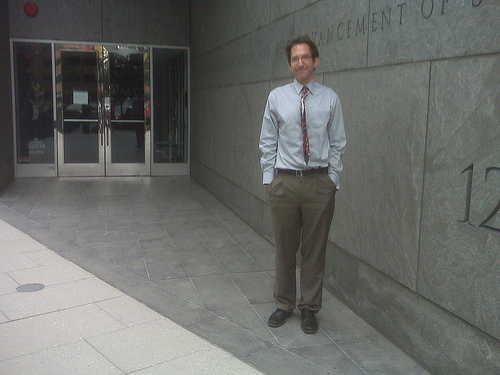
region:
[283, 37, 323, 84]
Man wearing eye glasses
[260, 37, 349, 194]
Man wearing glasses and tie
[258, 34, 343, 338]
Man wearing slacks, shirt, tie, and glasses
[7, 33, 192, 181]
Front door to a building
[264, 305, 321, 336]
Black shoes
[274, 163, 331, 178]
Black belt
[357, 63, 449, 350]
Granite side of a building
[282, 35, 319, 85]
Man with short hair smiling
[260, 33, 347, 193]
Man waring red tie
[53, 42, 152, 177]
Front glass door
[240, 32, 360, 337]
a man standing by the building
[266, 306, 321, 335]
the black dress shoes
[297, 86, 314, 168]
a red tie on the man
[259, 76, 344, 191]
a blue long sleeve shirt tucked in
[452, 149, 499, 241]
the number carved in the wall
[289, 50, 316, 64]
the eye glasses on the mans face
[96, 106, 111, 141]
the rails on the door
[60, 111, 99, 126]
the rail of the door behind the glass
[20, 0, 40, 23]
a red alarm above the door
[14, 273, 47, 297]
a round grate on the ground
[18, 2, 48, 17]
Alarm on the side of the building.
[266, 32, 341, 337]
Man standing outside the building.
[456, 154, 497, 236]
The number 12 on the side of a building.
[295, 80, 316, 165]
Tie on the man's neck.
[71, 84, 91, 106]
Sign on the front of the door.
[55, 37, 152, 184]
Glass doors to enter the building.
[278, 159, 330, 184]
Belt on the man's waist.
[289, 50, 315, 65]
Glasses on the man's face.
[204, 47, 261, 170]
Stones of the building.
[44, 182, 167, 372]
Concrete tile walkway to building.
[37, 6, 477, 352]
A man is standing at an office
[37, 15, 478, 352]
The man is in front of an office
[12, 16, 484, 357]
A man is taking a break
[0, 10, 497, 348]
The man is visiting somebody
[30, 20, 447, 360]
The man is smiling nice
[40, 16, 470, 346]
The man is wearing eyeglasses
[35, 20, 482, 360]
A man is wearing a neck tie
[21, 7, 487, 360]
A man has just left a meeting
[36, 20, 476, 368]
The man is going to a meeting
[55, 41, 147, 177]
The doors to a building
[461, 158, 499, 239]
a number on a wall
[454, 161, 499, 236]
a number on a concrete wall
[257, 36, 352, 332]
a man standing by a wall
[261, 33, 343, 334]
a man standing by a concrete wall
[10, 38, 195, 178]
A silver double door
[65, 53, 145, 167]
glass in the door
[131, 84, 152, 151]
reflections in the door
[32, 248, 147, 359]
concrete for flooring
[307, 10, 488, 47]
writing on a concrete wall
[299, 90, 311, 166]
a red and silver tie